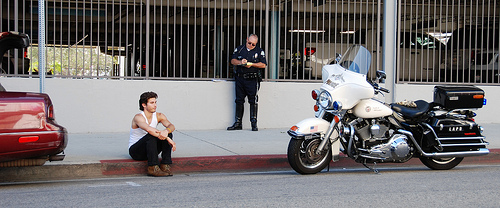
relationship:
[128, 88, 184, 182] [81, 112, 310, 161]
man sitting on sidewalk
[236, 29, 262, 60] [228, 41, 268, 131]
officer in uniform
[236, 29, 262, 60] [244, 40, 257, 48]
officer wearing sunglasses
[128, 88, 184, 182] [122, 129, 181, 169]
man wearing pants